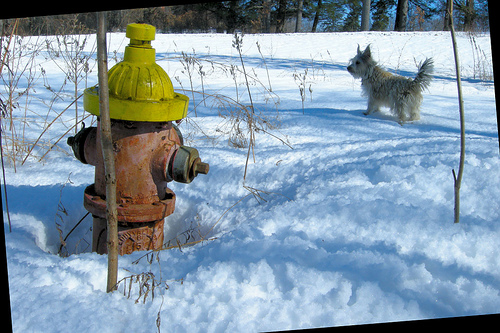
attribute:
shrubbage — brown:
[227, 31, 256, 113]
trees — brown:
[0, 3, 488, 34]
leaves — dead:
[113, 270, 170, 327]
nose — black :
[340, 62, 360, 84]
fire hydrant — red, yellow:
[66, 20, 211, 252]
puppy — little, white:
[346, 40, 433, 124]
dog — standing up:
[349, 45, 469, 135]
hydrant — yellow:
[30, 23, 222, 270]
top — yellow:
[82, 19, 191, 123]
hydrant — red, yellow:
[66, 20, 213, 255]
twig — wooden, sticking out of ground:
[445, 21, 480, 224]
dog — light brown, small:
[355, 53, 419, 105]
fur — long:
[367, 65, 407, 97]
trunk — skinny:
[444, 0, 466, 222]